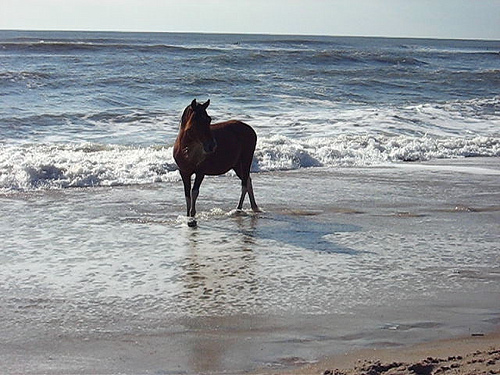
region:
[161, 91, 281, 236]
a brown horse in the ocean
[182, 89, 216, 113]
pointy ears of horse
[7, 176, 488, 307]
water is shallow in this part of the beach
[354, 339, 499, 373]
traces in the wet sand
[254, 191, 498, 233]
traces of feet of horse can be seen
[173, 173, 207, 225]
front legs of horse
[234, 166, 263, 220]
back leg of horse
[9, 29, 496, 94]
waves are forming in the ocean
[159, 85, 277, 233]
the head of the horse is to the right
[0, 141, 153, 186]
the seawater looks foamy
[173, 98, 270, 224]
a horse in the picture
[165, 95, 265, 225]
the horse is brown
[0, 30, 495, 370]
the horse is at the beach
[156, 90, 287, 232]
the horse is standing in water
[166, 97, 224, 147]
the head of a horse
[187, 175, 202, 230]
the foot of a horse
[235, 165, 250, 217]
the foot of a horse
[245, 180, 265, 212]
the foot of a horse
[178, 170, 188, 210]
the foot of a horse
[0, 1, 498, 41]
the sky at the background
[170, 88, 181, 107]
a brown horse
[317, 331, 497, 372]
trampled sand on the beach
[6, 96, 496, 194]
white waves coming into shore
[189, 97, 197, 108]
an ear on a horse's head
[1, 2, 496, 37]
a pale grey sky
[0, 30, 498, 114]
dark blue water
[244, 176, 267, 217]
a white leg behind a horse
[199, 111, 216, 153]
the muzzle of a horse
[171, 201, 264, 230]
water hitting a horse's legs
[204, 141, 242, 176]
the belly of a horse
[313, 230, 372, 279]
edge of a shore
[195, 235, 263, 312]
part of a water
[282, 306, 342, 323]
edge of a shore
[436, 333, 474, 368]
part of a beach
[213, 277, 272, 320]
edge of a water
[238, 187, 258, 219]
edge of a leg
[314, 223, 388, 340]
part of a shade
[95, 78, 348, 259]
horse standing on the beach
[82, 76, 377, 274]
beautiful horse standing on the beach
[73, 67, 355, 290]
dark horse standing on the beach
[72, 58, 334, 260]
healthy horse standing on the beach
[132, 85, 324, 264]
single horse standing on the beach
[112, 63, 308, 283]
nice horse standing on the beach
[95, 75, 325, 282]
nice looking horse standing on the beach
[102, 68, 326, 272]
attractive horse standing on the beach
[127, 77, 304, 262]
pretty looking horse standing on the beach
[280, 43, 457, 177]
some beautiful ocean water